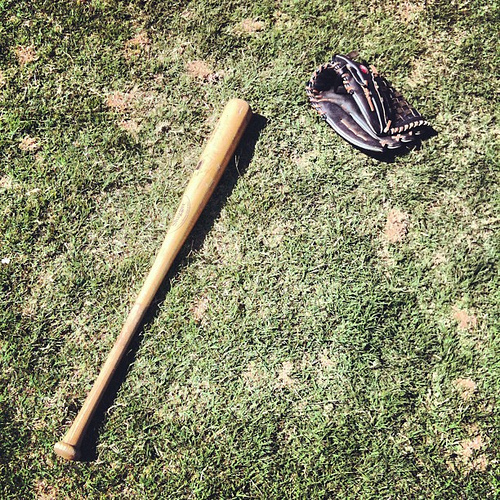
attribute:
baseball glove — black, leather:
[308, 57, 433, 159]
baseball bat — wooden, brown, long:
[54, 98, 253, 461]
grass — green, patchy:
[264, 190, 402, 324]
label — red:
[360, 62, 371, 77]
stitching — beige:
[389, 121, 430, 133]